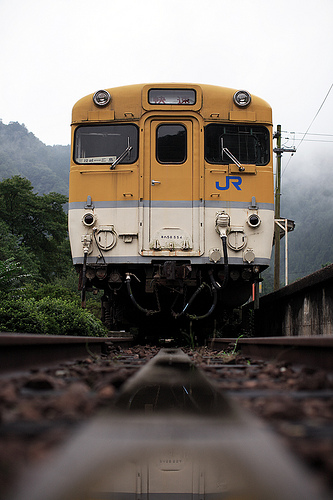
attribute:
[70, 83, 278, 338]
train — white, black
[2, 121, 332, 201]
mountains — foggy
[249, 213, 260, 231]
light — black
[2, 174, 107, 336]
trees — green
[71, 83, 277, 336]
bus — yellow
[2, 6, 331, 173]
sky — blue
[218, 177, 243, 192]
letter — blue